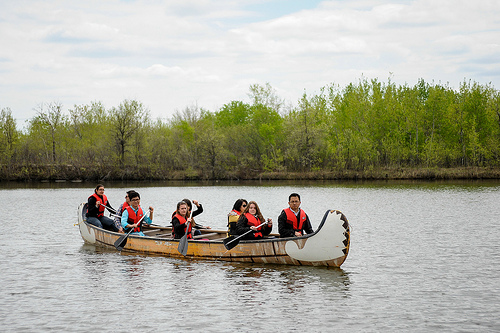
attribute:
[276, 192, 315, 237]
man — wearing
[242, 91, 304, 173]
tree — short, green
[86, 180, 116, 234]
woman — wearing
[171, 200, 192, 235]
person — riding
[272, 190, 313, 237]
person — riding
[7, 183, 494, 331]
water — still, under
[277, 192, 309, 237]
person — riding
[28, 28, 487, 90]
sky — distant